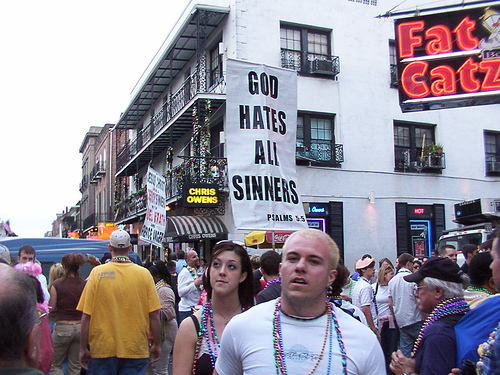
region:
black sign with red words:
[386, 13, 497, 126]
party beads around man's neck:
[255, 292, 358, 373]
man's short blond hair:
[278, 224, 359, 250]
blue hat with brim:
[396, 251, 475, 285]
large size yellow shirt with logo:
[75, 255, 162, 365]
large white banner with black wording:
[181, 33, 336, 238]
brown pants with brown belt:
[45, 312, 95, 371]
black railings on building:
[108, 73, 275, 123]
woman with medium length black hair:
[187, 233, 260, 304]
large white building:
[141, 2, 475, 319]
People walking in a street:
[8, 2, 497, 371]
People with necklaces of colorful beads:
[173, 246, 498, 369]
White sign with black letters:
[215, 55, 320, 231]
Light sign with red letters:
[396, 16, 497, 107]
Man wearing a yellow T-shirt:
[75, 228, 175, 373]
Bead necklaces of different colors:
[260, 295, 355, 372]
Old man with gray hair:
[397, 251, 467, 371]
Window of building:
[385, 112, 451, 173]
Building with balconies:
[102, 66, 223, 218]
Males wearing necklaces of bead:
[255, 235, 470, 373]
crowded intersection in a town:
[22, 42, 477, 349]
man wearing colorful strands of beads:
[235, 225, 386, 370]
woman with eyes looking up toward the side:
[170, 227, 275, 363]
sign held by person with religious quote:
[216, 51, 311, 261]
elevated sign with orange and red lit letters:
[390, 7, 495, 122]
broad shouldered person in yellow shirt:
[66, 230, 176, 365]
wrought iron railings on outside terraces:
[95, 25, 231, 221]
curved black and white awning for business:
[157, 205, 228, 245]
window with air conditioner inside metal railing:
[292, 17, 353, 92]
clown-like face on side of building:
[202, 153, 224, 184]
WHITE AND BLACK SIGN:
[209, 52, 324, 249]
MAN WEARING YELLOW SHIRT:
[62, 246, 165, 360]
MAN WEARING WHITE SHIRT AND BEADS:
[210, 227, 388, 373]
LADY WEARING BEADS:
[161, 227, 258, 369]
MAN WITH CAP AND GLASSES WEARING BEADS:
[400, 254, 470, 374]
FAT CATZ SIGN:
[385, 0, 498, 122]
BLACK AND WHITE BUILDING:
[225, 0, 498, 260]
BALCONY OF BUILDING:
[107, 59, 228, 184]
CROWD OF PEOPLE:
[2, 222, 498, 373]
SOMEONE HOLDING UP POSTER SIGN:
[135, 162, 167, 258]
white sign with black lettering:
[225, 59, 320, 229]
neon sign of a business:
[385, 9, 499, 110]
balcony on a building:
[103, 82, 226, 159]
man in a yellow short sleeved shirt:
[75, 240, 166, 358]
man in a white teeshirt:
[223, 247, 400, 367]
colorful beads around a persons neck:
[266, 287, 377, 374]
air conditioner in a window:
[411, 137, 466, 176]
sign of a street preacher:
[218, 53, 312, 241]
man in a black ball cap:
[405, 254, 468, 311]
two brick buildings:
[78, 134, 120, 217]